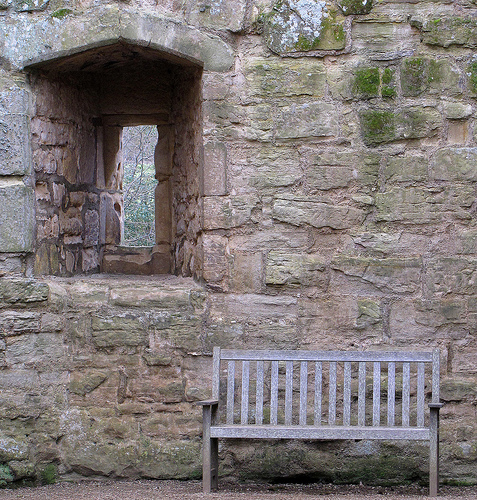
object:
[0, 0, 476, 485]
wall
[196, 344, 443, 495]
bench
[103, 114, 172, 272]
trees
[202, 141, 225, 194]
brick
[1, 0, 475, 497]
building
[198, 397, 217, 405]
arm rest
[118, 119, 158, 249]
window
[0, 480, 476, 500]
ground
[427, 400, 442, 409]
arm rest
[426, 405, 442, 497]
leg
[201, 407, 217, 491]
leg